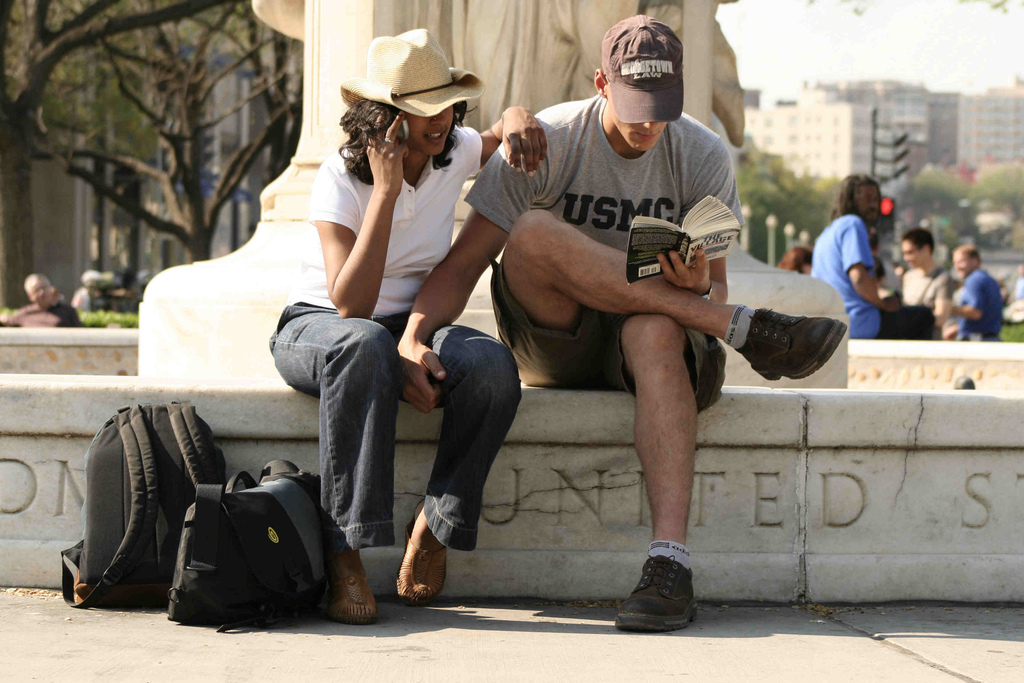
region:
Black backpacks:
[81, 405, 326, 637]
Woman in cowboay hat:
[296, 26, 508, 611]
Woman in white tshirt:
[272, 32, 501, 618]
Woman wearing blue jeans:
[283, 32, 525, 617]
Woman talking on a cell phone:
[278, 12, 523, 642]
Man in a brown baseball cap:
[493, 15, 849, 636]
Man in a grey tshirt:
[483, 6, 847, 635]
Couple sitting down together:
[274, 19, 843, 640]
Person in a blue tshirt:
[817, 177, 939, 346]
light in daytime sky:
[723, 5, 1021, 97]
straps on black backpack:
[63, 402, 216, 603]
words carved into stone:
[0, 381, 1021, 603]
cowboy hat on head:
[341, 21, 487, 178]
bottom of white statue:
[141, 1, 751, 369]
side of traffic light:
[866, 107, 912, 183]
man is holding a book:
[625, 191, 737, 291]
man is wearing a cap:
[596, 14, 695, 128]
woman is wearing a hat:
[335, 32, 487, 122]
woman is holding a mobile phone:
[362, 108, 417, 150]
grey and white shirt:
[487, 87, 737, 277]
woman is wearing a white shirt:
[284, 109, 493, 315]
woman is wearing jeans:
[269, 299, 503, 555]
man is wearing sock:
[641, 533, 696, 571]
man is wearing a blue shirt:
[795, 213, 882, 344]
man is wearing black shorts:
[482, 244, 727, 400]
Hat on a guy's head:
[583, 5, 701, 166]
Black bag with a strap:
[48, 386, 241, 620]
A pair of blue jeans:
[260, 291, 532, 555]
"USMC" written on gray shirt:
[457, 81, 748, 259]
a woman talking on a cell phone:
[265, 26, 551, 627]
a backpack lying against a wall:
[58, 399, 230, 614]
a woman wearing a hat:
[267, 27, 549, 628]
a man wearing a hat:
[395, 12, 851, 636]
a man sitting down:
[807, 172, 937, 341]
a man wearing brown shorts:
[392, 14, 849, 632]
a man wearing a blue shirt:
[945, 239, 1004, 342]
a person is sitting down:
[272, 30, 519, 616]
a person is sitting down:
[402, 14, 840, 622]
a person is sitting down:
[797, 166, 933, 338]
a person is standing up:
[883, 206, 961, 344]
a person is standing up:
[940, 232, 995, 346]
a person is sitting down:
[14, 266, 79, 327]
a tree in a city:
[4, 10, 305, 263]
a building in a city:
[810, 74, 934, 180]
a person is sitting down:
[296, 16, 516, 604]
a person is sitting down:
[393, 20, 821, 627]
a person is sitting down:
[1, 270, 85, 337]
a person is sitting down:
[800, 174, 931, 345]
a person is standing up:
[947, 226, 1008, 344]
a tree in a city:
[2, 0, 224, 275]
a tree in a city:
[4, 5, 286, 259]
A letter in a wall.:
[822, 465, 871, 541]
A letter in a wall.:
[746, 463, 782, 536]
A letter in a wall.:
[688, 465, 730, 524]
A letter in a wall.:
[626, 463, 655, 531]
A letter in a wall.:
[541, 459, 625, 523]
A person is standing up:
[945, 241, 999, 343]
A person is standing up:
[866, 226, 887, 269]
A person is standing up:
[784, 241, 826, 292]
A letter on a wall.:
[541, 459, 615, 540]